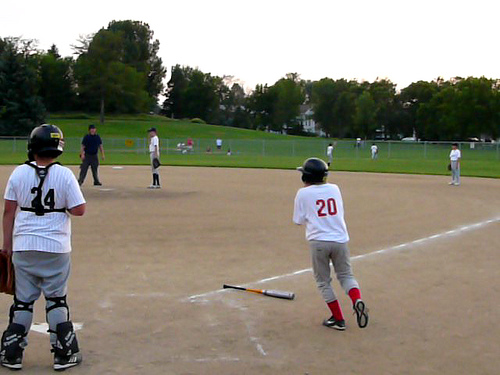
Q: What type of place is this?
A: It is a field.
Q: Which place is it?
A: It is a field.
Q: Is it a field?
A: Yes, it is a field.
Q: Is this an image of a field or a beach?
A: It is showing a field.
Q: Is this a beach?
A: No, it is a field.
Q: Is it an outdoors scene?
A: Yes, it is outdoors.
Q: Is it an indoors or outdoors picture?
A: It is outdoors.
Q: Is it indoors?
A: No, it is outdoors.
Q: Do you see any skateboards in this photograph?
A: No, there are no skateboards.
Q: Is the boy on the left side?
A: Yes, the boy is on the left of the image.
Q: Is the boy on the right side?
A: No, the boy is on the left of the image.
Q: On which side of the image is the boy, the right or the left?
A: The boy is on the left of the image.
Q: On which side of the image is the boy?
A: The boy is on the left of the image.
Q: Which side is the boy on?
A: The boy is on the left of the image.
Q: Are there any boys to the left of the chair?
A: Yes, there is a boy to the left of the chair.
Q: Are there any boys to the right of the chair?
A: No, the boy is to the left of the chair.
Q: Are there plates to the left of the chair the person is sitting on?
A: No, there is a boy to the left of the chair.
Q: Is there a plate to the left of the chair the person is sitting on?
A: No, there is a boy to the left of the chair.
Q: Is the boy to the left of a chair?
A: Yes, the boy is to the left of a chair.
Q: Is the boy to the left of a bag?
A: No, the boy is to the left of a chair.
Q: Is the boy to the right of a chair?
A: No, the boy is to the left of a chair.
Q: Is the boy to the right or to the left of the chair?
A: The boy is to the left of the chair.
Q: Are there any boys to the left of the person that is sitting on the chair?
A: Yes, there is a boy to the left of the person.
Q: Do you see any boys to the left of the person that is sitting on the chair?
A: Yes, there is a boy to the left of the person.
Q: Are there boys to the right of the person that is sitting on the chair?
A: No, the boy is to the left of the person.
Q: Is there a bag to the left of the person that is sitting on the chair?
A: No, there is a boy to the left of the person.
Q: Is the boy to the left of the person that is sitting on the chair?
A: Yes, the boy is to the left of the person.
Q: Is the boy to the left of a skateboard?
A: No, the boy is to the left of the person.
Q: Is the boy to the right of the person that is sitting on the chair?
A: No, the boy is to the left of the person.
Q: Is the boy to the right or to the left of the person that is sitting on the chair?
A: The boy is to the left of the person.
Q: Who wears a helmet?
A: The boy wears a helmet.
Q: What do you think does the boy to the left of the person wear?
A: The boy wears a helmet.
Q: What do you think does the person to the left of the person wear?
A: The boy wears a helmet.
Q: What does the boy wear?
A: The boy wears a helmet.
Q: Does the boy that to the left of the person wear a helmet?
A: Yes, the boy wears a helmet.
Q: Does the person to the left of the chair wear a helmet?
A: Yes, the boy wears a helmet.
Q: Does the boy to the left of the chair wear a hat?
A: No, the boy wears a helmet.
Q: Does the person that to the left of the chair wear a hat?
A: No, the boy wears a helmet.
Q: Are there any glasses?
A: No, there are no glasses.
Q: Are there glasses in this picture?
A: No, there are no glasses.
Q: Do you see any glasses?
A: No, there are no glasses.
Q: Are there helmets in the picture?
A: Yes, there is a helmet.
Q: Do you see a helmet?
A: Yes, there is a helmet.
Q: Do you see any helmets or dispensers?
A: Yes, there is a helmet.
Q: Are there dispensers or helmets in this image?
A: Yes, there is a helmet.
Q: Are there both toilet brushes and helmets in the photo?
A: No, there is a helmet but no toilet brushes.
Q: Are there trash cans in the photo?
A: No, there are no trash cans.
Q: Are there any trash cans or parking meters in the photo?
A: No, there are no trash cans or parking meters.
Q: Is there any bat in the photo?
A: Yes, there is a bat.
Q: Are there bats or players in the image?
A: Yes, there is a bat.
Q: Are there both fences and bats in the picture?
A: Yes, there are both a bat and a fence.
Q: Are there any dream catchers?
A: No, there are no dream catchers.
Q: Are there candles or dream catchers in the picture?
A: No, there are no dream catchers or candles.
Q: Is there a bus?
A: No, there are no buses.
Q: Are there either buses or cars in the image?
A: No, there are no buses or cars.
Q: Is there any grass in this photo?
A: Yes, there is grass.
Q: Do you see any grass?
A: Yes, there is grass.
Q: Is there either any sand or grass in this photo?
A: Yes, there is grass.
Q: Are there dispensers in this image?
A: No, there are no dispensers.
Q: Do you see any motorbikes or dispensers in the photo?
A: No, there are no dispensers or motorbikes.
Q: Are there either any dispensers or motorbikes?
A: No, there are no dispensers or motorbikes.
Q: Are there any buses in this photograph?
A: No, there are no buses.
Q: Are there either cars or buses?
A: No, there are no buses or cars.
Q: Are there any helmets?
A: Yes, there is a helmet.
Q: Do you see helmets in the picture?
A: Yes, there is a helmet.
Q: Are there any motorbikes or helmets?
A: Yes, there is a helmet.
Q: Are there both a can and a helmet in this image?
A: No, there is a helmet but no cans.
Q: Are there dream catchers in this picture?
A: No, there are no dream catchers.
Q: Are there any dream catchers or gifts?
A: No, there are no dream catchers or gifts.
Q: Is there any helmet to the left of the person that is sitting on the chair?
A: Yes, there is a helmet to the left of the person.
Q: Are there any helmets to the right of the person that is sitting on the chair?
A: No, the helmet is to the left of the person.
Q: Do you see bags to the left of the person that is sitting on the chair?
A: No, there is a helmet to the left of the person.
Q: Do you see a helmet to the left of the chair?
A: Yes, there is a helmet to the left of the chair.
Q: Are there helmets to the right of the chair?
A: No, the helmet is to the left of the chair.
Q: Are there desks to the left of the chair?
A: No, there is a helmet to the left of the chair.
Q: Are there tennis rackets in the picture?
A: No, there are no tennis rackets.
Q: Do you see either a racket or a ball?
A: No, there are no rackets or balls.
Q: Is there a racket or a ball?
A: No, there are no rackets or balls.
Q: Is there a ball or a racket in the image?
A: No, there are no rackets or balls.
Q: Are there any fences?
A: Yes, there is a fence.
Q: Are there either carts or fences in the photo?
A: Yes, there is a fence.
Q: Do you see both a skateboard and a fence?
A: No, there is a fence but no skateboards.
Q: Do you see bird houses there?
A: No, there are no bird houses.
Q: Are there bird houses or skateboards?
A: No, there are no bird houses or skateboards.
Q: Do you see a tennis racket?
A: No, there are no rackets.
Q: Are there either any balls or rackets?
A: No, there are no rackets or balls.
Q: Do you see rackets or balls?
A: No, there are no rackets or balls.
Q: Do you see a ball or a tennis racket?
A: No, there are no rackets or balls.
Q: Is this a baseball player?
A: Yes, this is a baseball player.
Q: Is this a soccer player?
A: No, this is a baseball player.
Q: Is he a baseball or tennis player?
A: This is a baseball player.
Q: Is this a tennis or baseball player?
A: This is a baseball player.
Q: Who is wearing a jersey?
A: The player is wearing a jersey.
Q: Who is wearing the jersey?
A: The player is wearing a jersey.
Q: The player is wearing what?
A: The player is wearing a jersey.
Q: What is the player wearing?
A: The player is wearing a jersey.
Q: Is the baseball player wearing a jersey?
A: Yes, the player is wearing a jersey.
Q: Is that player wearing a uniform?
A: No, the player is wearing a jersey.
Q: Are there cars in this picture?
A: No, there are no cars.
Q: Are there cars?
A: No, there are no cars.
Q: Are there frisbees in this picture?
A: No, there are no frisbees.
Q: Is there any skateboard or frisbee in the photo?
A: No, there are no frisbees or skateboards.